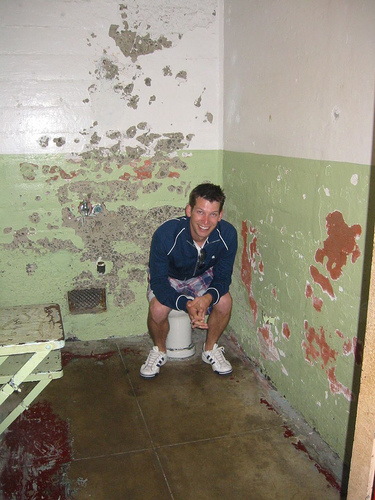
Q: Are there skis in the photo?
A: No, there are no skis.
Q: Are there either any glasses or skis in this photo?
A: No, there are no skis or glasses.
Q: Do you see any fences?
A: No, there are no fences.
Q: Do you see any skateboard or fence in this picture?
A: No, there are no fences or skateboards.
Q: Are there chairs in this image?
A: No, there are no chairs.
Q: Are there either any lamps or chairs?
A: No, there are no chairs or lamps.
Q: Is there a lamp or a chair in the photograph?
A: No, there are no chairs or lamps.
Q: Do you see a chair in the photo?
A: No, there are no chairs.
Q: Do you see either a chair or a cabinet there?
A: No, there are no chairs or cabinets.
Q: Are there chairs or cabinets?
A: No, there are no chairs or cabinets.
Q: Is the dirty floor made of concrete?
A: Yes, the floor is made of concrete.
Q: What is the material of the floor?
A: The floor is made of concrete.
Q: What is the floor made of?
A: The floor is made of concrete.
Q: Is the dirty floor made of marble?
A: No, the floor is made of cement.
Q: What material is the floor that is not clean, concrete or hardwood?
A: The floor is made of concrete.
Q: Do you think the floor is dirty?
A: Yes, the floor is dirty.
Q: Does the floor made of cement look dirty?
A: Yes, the floor is dirty.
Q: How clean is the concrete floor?
A: The floor is dirty.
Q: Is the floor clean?
A: No, the floor is dirty.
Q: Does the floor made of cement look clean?
A: No, the floor is dirty.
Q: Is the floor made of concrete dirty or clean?
A: The floor is dirty.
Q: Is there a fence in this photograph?
A: No, there are no fences.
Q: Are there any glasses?
A: No, there are no glasses.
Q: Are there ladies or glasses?
A: No, there are no glasses or ladies.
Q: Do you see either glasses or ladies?
A: No, there are no glasses or ladies.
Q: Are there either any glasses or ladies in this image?
A: No, there are no glasses or ladies.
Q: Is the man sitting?
A: Yes, the man is sitting.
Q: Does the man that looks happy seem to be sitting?
A: Yes, the man is sitting.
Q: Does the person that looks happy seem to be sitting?
A: Yes, the man is sitting.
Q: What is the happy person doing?
A: The man is sitting.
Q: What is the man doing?
A: The man is sitting.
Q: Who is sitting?
A: The man is sitting.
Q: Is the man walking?
A: No, the man is sitting.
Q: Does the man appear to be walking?
A: No, the man is sitting.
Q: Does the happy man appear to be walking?
A: No, the man is sitting.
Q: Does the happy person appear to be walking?
A: No, the man is sitting.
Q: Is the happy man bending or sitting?
A: The man is sitting.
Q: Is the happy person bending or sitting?
A: The man is sitting.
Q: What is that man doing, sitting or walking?
A: The man is sitting.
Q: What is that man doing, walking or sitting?
A: The man is sitting.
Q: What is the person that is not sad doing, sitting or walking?
A: The man is sitting.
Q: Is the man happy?
A: Yes, the man is happy.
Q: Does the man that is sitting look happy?
A: Yes, the man is happy.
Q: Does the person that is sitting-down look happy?
A: Yes, the man is happy.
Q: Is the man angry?
A: No, the man is happy.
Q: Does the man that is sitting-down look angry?
A: No, the man is happy.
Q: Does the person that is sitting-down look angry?
A: No, the man is happy.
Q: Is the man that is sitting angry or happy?
A: The man is happy.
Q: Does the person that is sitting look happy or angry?
A: The man is happy.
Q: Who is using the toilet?
A: The man is using the toilet.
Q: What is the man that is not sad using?
A: The man is using a toilet.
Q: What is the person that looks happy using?
A: The man is using a toilet.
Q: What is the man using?
A: The man is using a toilet.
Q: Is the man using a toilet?
A: Yes, the man is using a toilet.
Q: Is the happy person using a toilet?
A: Yes, the man is using a toilet.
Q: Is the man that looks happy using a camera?
A: No, the man is using a toilet.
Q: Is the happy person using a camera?
A: No, the man is using a toilet.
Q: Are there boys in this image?
A: No, there are no boys.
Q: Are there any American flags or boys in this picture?
A: No, there are no boys or American flags.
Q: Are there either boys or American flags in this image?
A: No, there are no boys or American flags.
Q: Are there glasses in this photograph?
A: No, there are no glasses.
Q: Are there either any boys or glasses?
A: No, there are no glasses or boys.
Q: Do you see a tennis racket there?
A: No, there are no rackets.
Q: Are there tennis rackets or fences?
A: No, there are no tennis rackets or fences.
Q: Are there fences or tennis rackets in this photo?
A: No, there are no tennis rackets or fences.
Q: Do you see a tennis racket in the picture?
A: No, there are no rackets.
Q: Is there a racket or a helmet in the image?
A: No, there are no rackets or helmets.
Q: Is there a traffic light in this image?
A: No, there are no traffic lights.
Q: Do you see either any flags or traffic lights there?
A: No, there are no traffic lights or flags.